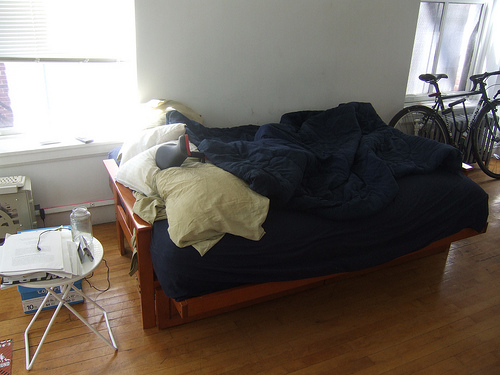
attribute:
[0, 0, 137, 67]
blind — white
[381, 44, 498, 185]
bicycle —  Blue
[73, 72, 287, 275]
pillow — White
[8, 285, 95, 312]
box — card board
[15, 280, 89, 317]
cardboard box — blue and white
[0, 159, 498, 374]
floor —  wooden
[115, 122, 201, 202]
pillow cases — White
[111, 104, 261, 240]
pillows — White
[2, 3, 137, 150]
window — Luminous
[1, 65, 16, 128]
brick wall — Solid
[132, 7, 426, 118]
wall — white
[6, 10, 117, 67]
white blinds —  white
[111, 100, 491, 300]
comforter — Black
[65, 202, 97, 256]
mason jar — Clear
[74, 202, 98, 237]
jar — clear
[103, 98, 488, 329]
bed — Blue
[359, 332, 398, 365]
flooring — wooden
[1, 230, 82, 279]
papers — White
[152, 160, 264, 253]
pillow — big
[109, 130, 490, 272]
mattress — queen sized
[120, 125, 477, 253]
sheets — navy blue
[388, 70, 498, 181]
bicycle — Blue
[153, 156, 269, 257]
pillow — yellow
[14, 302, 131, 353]
metal — white